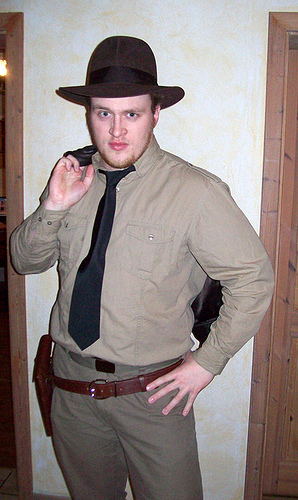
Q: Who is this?
A: Man.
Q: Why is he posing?
A: Picture.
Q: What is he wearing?
A: Hat.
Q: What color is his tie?
A: Black.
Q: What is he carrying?
A: Coat.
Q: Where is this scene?
A: By the doors.